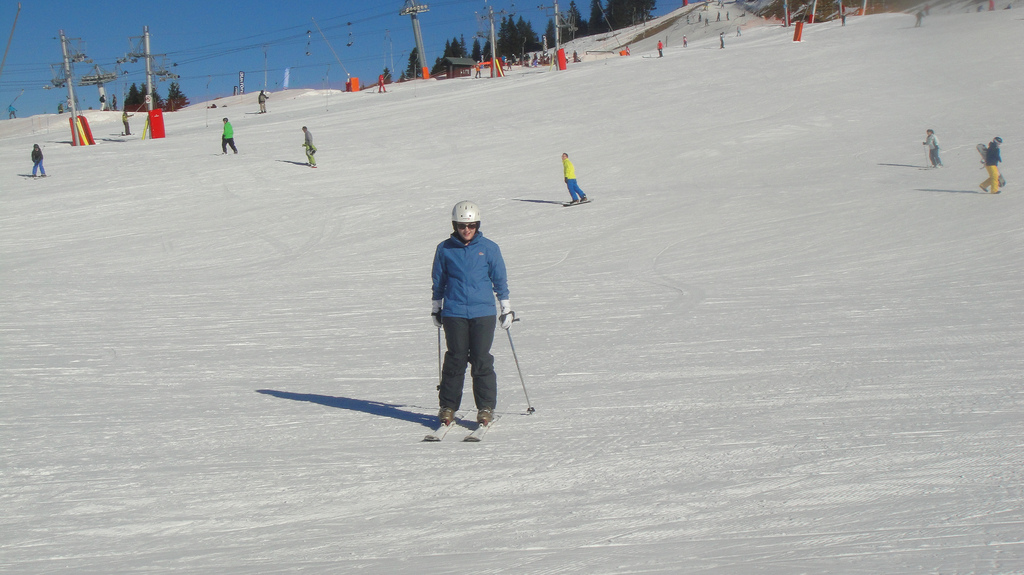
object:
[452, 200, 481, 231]
helmet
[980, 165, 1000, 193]
pants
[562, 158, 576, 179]
jacket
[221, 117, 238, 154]
snowboarder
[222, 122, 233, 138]
jacket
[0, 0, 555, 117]
skilift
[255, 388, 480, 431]
shadow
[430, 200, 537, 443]
skier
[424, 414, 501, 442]
skis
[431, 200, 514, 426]
person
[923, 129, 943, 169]
skier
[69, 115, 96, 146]
pad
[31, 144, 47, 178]
person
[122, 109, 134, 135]
person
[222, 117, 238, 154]
person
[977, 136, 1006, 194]
person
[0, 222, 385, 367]
snow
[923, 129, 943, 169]
person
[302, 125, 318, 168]
person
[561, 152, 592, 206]
person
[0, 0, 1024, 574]
snow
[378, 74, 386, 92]
person